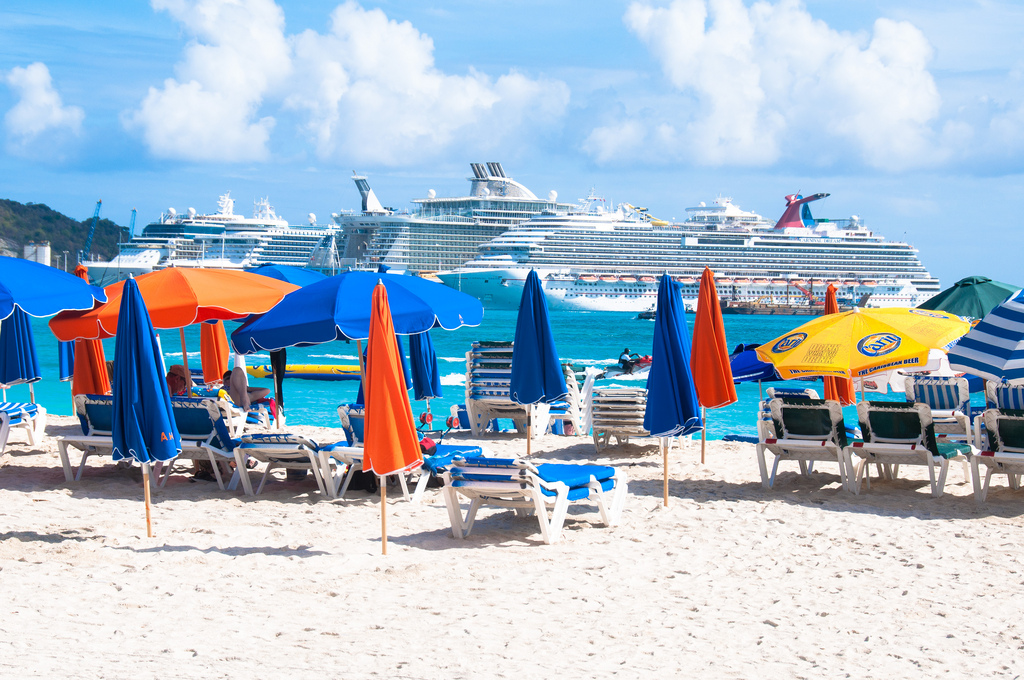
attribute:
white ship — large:
[70, 146, 937, 306]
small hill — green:
[5, 194, 132, 262]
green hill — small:
[5, 192, 129, 259]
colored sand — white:
[6, 403, 1022, 667]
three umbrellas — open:
[498, 270, 737, 432]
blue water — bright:
[173, 315, 885, 442]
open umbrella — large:
[40, 248, 303, 362]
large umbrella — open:
[228, 257, 501, 369]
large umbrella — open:
[347, 274, 449, 563]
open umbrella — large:
[755, 280, 987, 404]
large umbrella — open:
[487, 255, 586, 455]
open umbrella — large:
[244, 255, 480, 380]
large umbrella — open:
[626, 242, 703, 459]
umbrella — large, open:
[635, 253, 696, 476]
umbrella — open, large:
[682, 238, 729, 462]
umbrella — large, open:
[497, 253, 607, 522]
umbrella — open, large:
[331, 275, 475, 555]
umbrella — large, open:
[103, 252, 207, 484]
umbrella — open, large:
[56, 241, 111, 435]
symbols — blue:
[767, 327, 906, 364]